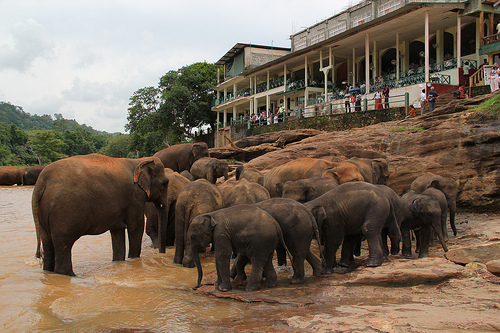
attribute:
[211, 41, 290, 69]
roof — flat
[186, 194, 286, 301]
elephant — standing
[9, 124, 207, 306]
elephant — large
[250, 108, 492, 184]
rocky background — steep, jagged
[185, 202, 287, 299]
elephant — gray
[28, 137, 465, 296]
elephants — grouped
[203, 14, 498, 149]
building — three story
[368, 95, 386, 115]
skirt — red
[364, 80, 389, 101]
top — white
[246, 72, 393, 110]
crowd — watching